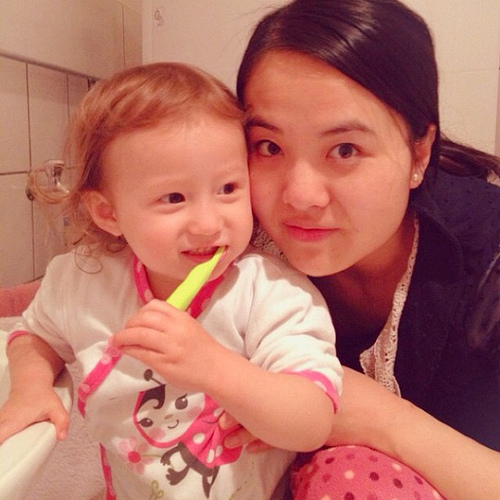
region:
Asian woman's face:
[231, 3, 461, 278]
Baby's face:
[58, 62, 257, 289]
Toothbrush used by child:
[147, 245, 234, 343]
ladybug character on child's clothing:
[119, 363, 274, 489]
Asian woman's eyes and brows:
[249, 119, 382, 171]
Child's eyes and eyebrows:
[126, 173, 252, 214]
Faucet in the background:
[18, 154, 73, 211]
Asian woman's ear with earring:
[406, 127, 440, 205]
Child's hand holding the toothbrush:
[111, 298, 231, 389]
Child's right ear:
[75, 187, 128, 252]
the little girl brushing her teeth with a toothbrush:
[152, 243, 222, 318]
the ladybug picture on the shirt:
[127, 364, 245, 485]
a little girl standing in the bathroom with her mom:
[29, 61, 494, 498]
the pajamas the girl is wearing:
[33, 256, 423, 498]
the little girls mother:
[232, 7, 499, 482]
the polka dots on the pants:
[292, 440, 429, 499]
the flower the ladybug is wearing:
[114, 433, 158, 467]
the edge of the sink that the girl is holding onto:
[0, 316, 56, 493]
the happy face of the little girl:
[101, 114, 261, 288]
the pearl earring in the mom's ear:
[406, 168, 422, 185]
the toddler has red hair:
[29, 59, 249, 281]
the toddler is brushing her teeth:
[88, 61, 250, 368]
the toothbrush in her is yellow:
[161, 241, 235, 325]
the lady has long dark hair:
[238, 0, 499, 278]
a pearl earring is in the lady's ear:
[409, 163, 428, 195]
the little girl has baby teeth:
[183, 243, 224, 262]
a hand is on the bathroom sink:
[3, 303, 105, 489]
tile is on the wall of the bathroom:
[2, 60, 115, 297]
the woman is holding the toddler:
[113, 28, 499, 478]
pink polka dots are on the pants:
[289, 443, 444, 498]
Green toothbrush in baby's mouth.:
[174, 247, 245, 319]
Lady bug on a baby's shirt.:
[127, 368, 253, 484]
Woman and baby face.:
[83, 29, 415, 287]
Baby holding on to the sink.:
[0, 305, 75, 487]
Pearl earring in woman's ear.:
[405, 168, 428, 189]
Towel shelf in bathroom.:
[29, 151, 76, 212]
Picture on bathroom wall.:
[144, 4, 179, 39]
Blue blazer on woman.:
[419, 192, 494, 439]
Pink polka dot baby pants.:
[288, 447, 394, 493]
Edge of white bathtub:
[3, 315, 71, 499]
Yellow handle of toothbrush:
[156, 244, 226, 316]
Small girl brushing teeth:
[18, 69, 346, 494]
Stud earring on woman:
[406, 165, 421, 188]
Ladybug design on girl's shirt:
[130, 367, 242, 494]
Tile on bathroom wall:
[4, 66, 99, 283]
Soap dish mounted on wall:
[22, 160, 77, 215]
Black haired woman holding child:
[236, 4, 494, 499]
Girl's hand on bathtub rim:
[2, 319, 74, 451]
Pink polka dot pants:
[293, 441, 441, 499]